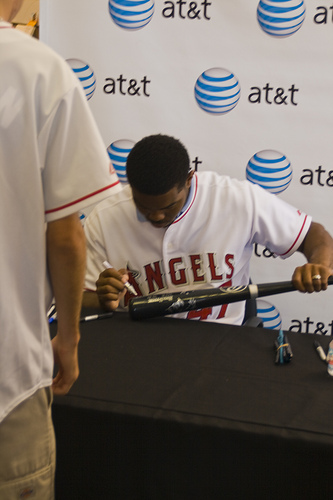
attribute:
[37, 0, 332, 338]
banner — background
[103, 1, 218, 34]
at&t — white, blue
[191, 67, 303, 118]
at&t — white, blue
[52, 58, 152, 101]
at&t — white, blue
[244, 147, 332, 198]
at&t — white, blue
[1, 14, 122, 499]
man — white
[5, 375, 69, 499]
shorts — beige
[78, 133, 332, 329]
man — baseball player, black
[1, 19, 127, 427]
shirt — white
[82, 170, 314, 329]
shirt — white, jersey, red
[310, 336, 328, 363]
pen — black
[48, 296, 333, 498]
table — black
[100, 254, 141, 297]
pen — white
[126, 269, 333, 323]
baseball bat — metal, black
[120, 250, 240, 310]
angels — red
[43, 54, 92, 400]
arm — skinny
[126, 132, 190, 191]
hair — black